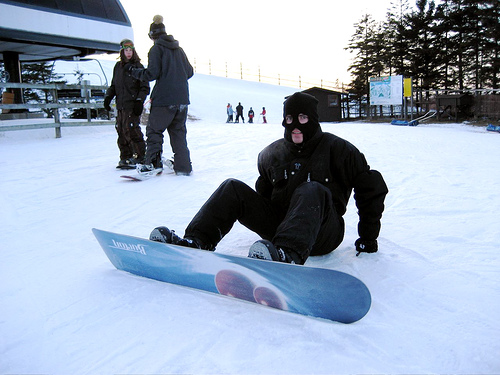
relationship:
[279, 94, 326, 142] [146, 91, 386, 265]
head of man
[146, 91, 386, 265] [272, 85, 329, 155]
man wearing mask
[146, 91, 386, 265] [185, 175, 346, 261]
man wearing pants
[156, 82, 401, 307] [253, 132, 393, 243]
man wearing jacket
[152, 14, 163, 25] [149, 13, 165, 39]
pompom on hat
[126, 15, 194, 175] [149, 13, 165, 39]
guy wearing hat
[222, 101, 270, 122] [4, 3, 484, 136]
people in distance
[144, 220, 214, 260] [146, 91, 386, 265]
feet of man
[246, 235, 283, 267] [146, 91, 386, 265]
foot of man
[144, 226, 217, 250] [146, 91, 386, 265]
feet of man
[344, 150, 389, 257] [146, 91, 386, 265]
arm of man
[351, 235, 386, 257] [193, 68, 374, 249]
hand of person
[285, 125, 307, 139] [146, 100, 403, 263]
mouth of person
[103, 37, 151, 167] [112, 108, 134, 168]
person has leg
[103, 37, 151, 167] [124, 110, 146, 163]
person has leg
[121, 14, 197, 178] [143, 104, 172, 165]
person has leg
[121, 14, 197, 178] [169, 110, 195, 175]
person has leg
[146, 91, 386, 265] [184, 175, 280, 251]
man has leg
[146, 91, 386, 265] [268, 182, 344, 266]
man has leg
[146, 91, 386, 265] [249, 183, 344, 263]
man has leg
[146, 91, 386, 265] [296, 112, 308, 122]
man has eye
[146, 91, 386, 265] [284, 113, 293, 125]
man has eye